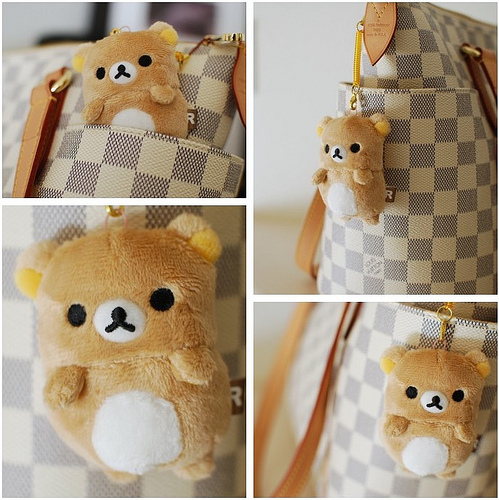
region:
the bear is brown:
[26, 229, 242, 491]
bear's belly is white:
[96, 385, 209, 494]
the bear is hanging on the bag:
[309, 16, 406, 268]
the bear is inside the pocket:
[68, 36, 188, 170]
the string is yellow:
[347, 25, 366, 96]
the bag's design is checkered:
[408, 83, 479, 236]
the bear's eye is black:
[148, 276, 177, 338]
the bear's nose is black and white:
[87, 292, 144, 361]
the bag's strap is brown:
[15, 76, 60, 182]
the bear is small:
[305, 69, 414, 242]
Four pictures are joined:
[24, 31, 471, 435]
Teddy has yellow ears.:
[13, 228, 236, 294]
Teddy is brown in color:
[11, 214, 237, 485]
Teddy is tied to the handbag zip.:
[307, 7, 418, 255]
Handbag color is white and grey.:
[395, 127, 469, 238]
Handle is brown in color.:
[464, 33, 498, 86]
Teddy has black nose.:
[104, 297, 132, 335]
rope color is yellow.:
[347, 26, 374, 85]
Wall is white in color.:
[282, 28, 330, 129]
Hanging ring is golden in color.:
[422, 299, 483, 348]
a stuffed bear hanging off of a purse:
[315, 20, 404, 218]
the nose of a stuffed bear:
[331, 144, 349, 160]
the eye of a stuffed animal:
[144, 281, 186, 313]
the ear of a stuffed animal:
[172, 208, 224, 262]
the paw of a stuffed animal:
[169, 346, 218, 378]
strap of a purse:
[270, 318, 372, 437]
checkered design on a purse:
[421, 119, 478, 225]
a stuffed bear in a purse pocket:
[72, 42, 193, 148]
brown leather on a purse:
[367, 7, 399, 61]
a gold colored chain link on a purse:
[432, 304, 461, 341]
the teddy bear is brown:
[379, 341, 481, 482]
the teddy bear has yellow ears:
[383, 347, 488, 374]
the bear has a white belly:
[400, 436, 448, 470]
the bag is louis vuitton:
[363, 254, 388, 280]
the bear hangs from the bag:
[325, 21, 389, 222]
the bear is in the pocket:
[55, 24, 246, 195]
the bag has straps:
[461, 40, 498, 111]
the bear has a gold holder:
[434, 304, 451, 343]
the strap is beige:
[253, 299, 364, 495]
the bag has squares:
[299, 15, 490, 290]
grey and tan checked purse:
[332, 5, 488, 289]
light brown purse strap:
[7, 93, 55, 190]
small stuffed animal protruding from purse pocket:
[63, 11, 195, 168]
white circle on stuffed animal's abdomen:
[87, 381, 187, 473]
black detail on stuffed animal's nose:
[97, 300, 130, 329]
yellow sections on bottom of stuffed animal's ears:
[371, 351, 483, 366]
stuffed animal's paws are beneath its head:
[367, 411, 478, 435]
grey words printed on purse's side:
[355, 248, 384, 279]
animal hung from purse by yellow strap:
[343, 16, 364, 115]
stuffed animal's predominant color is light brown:
[59, 237, 178, 284]